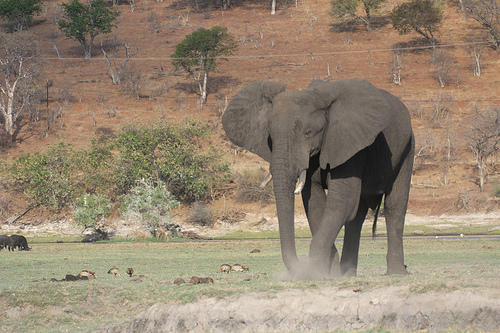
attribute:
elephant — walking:
[172, 69, 423, 286]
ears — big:
[227, 81, 417, 174]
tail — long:
[361, 195, 386, 245]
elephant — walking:
[205, 64, 443, 304]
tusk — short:
[291, 171, 305, 194]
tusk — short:
[257, 174, 271, 199]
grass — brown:
[235, 11, 384, 83]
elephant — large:
[221, 80, 417, 285]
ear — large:
[224, 80, 284, 158]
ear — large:
[315, 82, 385, 176]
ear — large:
[224, 84, 278, 160]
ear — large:
[313, 93, 385, 173]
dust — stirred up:
[188, 249, 430, 321]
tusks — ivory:
[227, 160, 337, 204]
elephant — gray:
[221, 77, 445, 292]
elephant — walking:
[211, 65, 480, 314]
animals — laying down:
[61, 246, 314, 302]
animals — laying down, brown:
[43, 262, 273, 311]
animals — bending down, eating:
[12, 226, 64, 265]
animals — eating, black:
[7, 230, 63, 270]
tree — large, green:
[28, 120, 262, 259]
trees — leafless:
[415, 96, 494, 187]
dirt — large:
[55, 58, 495, 220]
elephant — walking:
[224, 81, 477, 330]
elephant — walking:
[186, 62, 438, 319]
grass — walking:
[210, 221, 496, 280]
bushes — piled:
[40, 139, 196, 204]